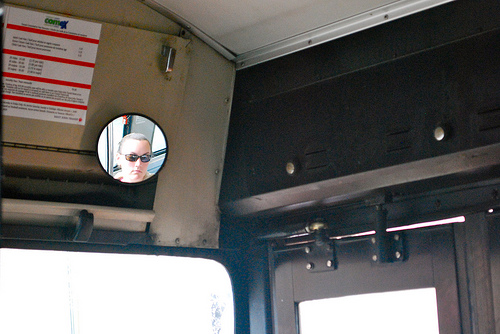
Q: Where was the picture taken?
A: On a bus.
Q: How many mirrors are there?
A: One.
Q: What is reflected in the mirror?
A: A man.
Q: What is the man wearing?
A: Sunglasses.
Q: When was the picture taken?
A: Daytime.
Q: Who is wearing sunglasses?
A: The man.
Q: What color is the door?
A: Black.